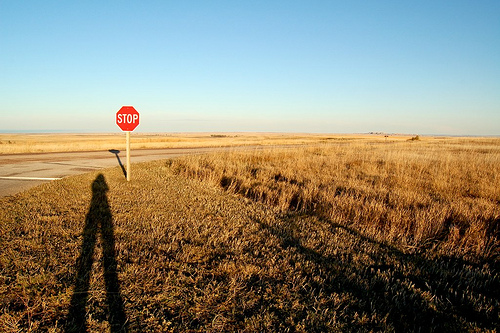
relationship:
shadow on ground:
[61, 169, 137, 332] [3, 151, 441, 329]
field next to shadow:
[172, 140, 499, 330] [61, 169, 137, 332]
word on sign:
[117, 113, 139, 124] [111, 101, 142, 132]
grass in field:
[226, 131, 495, 275] [179, 146, 498, 297]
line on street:
[2, 164, 54, 185] [4, 151, 253, 225]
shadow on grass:
[150, 238, 279, 292] [6, 158, 498, 332]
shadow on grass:
[61, 173, 125, 333] [6, 158, 498, 332]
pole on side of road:
[117, 125, 137, 185] [4, 151, 285, 214]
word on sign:
[117, 113, 139, 124] [112, 100, 142, 136]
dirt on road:
[8, 147, 178, 161] [2, 156, 196, 210]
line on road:
[0, 176, 64, 183] [2, 151, 200, 240]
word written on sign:
[117, 104, 140, 129] [112, 105, 148, 135]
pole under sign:
[125, 131, 131, 182] [108, 100, 150, 132]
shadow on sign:
[105, 147, 130, 177] [114, 100, 137, 168]